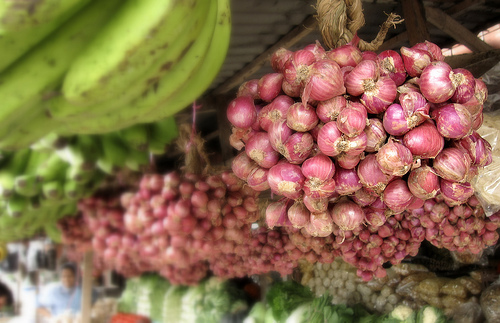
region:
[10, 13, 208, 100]
green plantains hanging from ceiling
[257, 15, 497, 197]
group of pink onions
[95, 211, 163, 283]
group of pink onions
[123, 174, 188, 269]
group of pink onions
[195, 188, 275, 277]
group of pink onions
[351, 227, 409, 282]
group of pink onions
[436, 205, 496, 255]
group of pink onions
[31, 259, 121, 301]
person in blue at market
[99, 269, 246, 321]
green celery and lettuce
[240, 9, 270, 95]
metal roof of market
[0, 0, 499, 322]
a fruit and vegetable market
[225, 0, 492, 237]
a bunch of onions hanging from the ceiling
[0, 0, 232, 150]
a bunch of bananas hanging from the ceiling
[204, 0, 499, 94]
ceiling of the marketplace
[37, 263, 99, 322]
a man in the background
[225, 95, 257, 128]
a red onion on the bunch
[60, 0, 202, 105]
a green banana on the bunch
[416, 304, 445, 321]
a green vegetable for sale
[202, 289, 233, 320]
a green vegetable for sale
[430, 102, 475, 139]
a red onion on the bunch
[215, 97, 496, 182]
onions are growing in a bushel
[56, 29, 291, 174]
plaintains are growing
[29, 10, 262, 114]
plantains are growing in a bushel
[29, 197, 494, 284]
several bushels are growing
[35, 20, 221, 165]
the plantains are green and black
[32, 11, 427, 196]
the plantains are hanging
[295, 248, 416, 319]
wood is underneath the onions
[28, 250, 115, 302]
a man is by the stand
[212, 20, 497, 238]
a bunch of onions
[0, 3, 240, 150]
a collection of bananas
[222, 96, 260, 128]
red onions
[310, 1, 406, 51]
a rope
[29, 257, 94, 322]
person wearing a shirt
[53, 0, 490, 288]
bunch of onions hanged by a rope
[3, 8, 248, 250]
bunch of bananas hanged on top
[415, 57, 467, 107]
a big onion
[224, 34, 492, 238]
a ball of onions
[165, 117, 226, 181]
rope used to hanged onion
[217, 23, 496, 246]
Bunch of red onions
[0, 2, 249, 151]
Bunch of green bananas hanging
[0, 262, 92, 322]
Two people in the distance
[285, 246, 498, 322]
Bags of food in the distance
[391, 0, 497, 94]
Brown support beams on the roof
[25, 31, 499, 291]
Many rows of hanging onions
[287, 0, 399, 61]
Brown piece of rope to hold onions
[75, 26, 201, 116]
Brown spots on green bananas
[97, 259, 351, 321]
More bags of food under onions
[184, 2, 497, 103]
Black metal roof